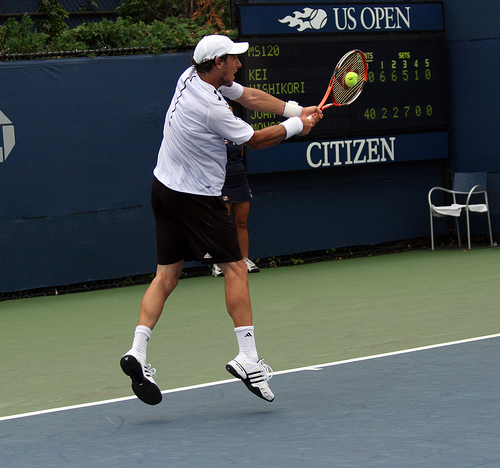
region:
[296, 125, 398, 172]
white word CITIZEN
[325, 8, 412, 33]
white words US OPEN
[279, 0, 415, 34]
US Open corporate logo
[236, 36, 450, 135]
an electronic score board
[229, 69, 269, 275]
a woman standing in back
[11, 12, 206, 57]
a large green bush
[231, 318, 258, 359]
a white man's sock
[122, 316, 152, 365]
a white man's sock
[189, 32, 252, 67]
a white billed cap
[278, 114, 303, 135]
a white wrist band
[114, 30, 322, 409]
a young man jumping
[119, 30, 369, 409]
a tennis player hitting ball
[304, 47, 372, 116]
a red and silver tennis racket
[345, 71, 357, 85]
a yellow tennis ball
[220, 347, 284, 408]
black and white tennis shoe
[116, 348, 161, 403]
black and white tennis shoe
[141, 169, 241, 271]
men's black short pants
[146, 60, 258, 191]
a white short sleeve shirt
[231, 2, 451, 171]
a game score board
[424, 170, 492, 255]
a small plastic chair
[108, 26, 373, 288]
A man hitting a tennis ball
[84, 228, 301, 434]
both of man's feet off ground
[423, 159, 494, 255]
a grey and silver chair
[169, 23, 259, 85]
man wearing a white hat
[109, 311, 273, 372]
a pair of addidas socks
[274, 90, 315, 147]
two white wrist bands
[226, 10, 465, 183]
a sign that shows the score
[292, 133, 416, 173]
the word citizen in white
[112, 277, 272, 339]
leg calfs with tight muscles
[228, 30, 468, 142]
an electric score board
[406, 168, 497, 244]
towel on the chair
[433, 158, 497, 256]
chair is blue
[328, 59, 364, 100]
tennis ball is yelow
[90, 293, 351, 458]
tennis player is in the air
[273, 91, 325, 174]
tennis player is wearing wristbands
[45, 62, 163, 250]
tennis wall is blue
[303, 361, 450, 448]
tennis court is blue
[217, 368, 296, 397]
three stripes on the sneakers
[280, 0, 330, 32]
picture of tennis ball with flame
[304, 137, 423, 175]
CITIZEN written in white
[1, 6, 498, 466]
man on a tennis court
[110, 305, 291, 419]
man's feet are off the ground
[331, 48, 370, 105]
tennis racket making contact with ball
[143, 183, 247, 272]
man wearing black shorts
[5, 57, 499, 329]
blue wall at border of tennis court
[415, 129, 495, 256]
chair beside wall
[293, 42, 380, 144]
man holding racket with both hands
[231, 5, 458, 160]
tennis scores displayed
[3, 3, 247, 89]
plants visible over wall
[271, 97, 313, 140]
man wearing white wrist bands